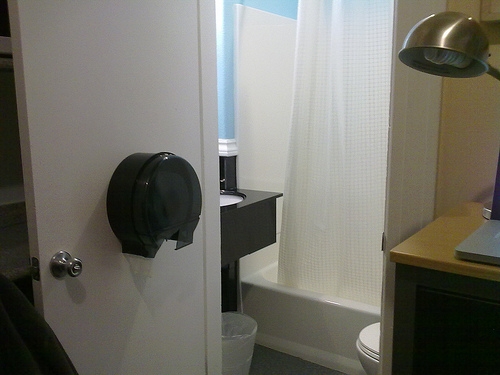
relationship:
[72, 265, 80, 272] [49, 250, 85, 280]
lock on knob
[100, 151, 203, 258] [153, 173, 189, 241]
holder for toilet paper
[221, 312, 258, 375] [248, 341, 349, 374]
bag on floor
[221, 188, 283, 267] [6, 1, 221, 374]
counter behind door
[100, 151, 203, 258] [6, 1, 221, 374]
holder on door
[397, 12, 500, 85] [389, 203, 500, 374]
lamp on shelf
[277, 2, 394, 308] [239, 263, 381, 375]
curtain in bathtub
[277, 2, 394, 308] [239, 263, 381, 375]
curtain above bathtub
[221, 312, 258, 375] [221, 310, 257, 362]
bag has a bag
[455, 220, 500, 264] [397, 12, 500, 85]
base of lamp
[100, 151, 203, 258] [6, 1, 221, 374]
holder hanging on door